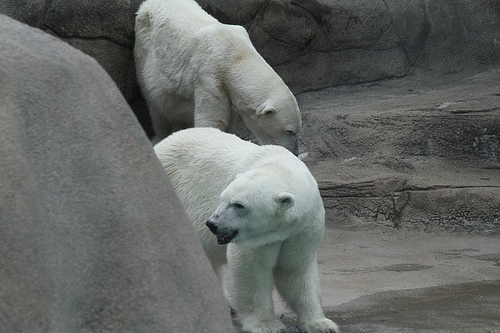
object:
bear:
[152, 126, 338, 332]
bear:
[134, 0, 301, 157]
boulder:
[2, 15, 235, 329]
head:
[250, 89, 302, 155]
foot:
[299, 311, 342, 332]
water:
[339, 294, 492, 331]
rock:
[206, 1, 497, 95]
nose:
[202, 219, 220, 233]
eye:
[230, 201, 246, 209]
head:
[206, 166, 296, 247]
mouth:
[207, 226, 241, 247]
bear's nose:
[204, 218, 224, 235]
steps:
[298, 71, 498, 228]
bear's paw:
[303, 326, 342, 331]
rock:
[0, 11, 242, 330]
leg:
[277, 211, 325, 319]